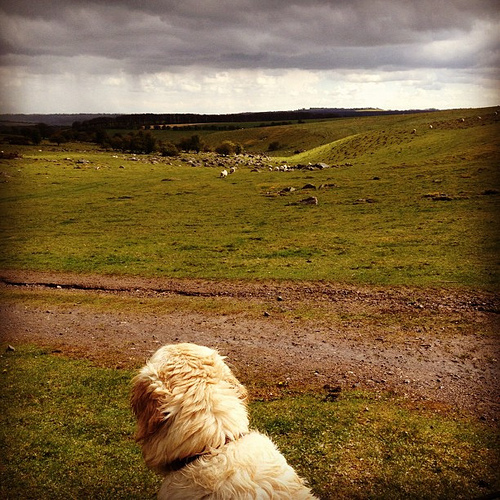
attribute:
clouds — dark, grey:
[0, 2, 496, 101]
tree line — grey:
[0, 112, 115, 126]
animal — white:
[216, 162, 232, 179]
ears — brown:
[131, 375, 168, 457]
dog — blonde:
[105, 324, 342, 484]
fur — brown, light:
[135, 342, 307, 498]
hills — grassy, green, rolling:
[19, 105, 496, 275]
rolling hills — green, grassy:
[2, 116, 497, 297]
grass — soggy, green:
[0, 106, 497, 497]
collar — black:
[150, 427, 267, 474]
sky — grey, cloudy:
[1, 0, 498, 113]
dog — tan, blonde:
[122, 332, 321, 497]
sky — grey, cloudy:
[244, 11, 335, 65]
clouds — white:
[5, 64, 461, 92]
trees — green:
[143, 122, 153, 131]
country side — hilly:
[9, 101, 497, 498]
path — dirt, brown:
[8, 259, 489, 430]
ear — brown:
[124, 371, 165, 439]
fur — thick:
[184, 386, 230, 429]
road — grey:
[8, 263, 480, 413]